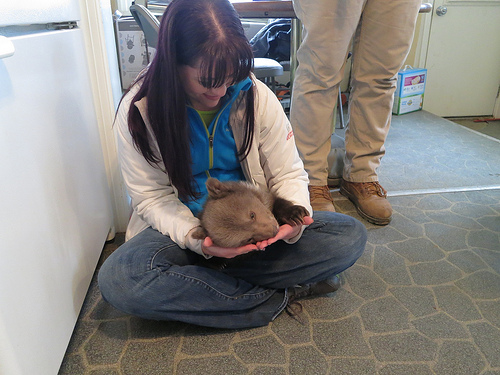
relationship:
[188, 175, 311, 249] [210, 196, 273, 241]
bear has head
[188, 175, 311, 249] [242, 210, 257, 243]
bear has eye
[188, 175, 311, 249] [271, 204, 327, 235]
bear has paw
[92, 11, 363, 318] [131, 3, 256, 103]
woman has head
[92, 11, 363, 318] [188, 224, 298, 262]
woman has hand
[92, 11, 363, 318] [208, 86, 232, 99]
woman has nose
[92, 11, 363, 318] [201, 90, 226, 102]
woman has mouth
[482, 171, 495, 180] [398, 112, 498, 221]
stone on floor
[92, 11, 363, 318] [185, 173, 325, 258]
woman holds bear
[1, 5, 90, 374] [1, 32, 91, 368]
fridge has door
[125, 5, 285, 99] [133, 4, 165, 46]
chair has back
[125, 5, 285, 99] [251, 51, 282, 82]
chair has front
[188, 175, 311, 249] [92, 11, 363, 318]
bear with woman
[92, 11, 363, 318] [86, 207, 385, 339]
woman wears jeans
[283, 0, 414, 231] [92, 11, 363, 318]
person near woman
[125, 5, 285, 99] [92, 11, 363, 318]
chair behind woman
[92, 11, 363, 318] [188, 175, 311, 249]
woman holds bear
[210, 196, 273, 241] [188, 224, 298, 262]
head in hands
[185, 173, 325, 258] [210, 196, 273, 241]
bear has head